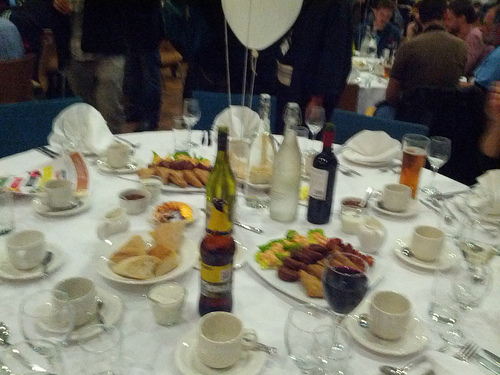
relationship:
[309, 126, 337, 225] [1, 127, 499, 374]
bottle on table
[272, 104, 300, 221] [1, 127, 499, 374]
clear bottle on table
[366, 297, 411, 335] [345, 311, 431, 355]
cup on small plate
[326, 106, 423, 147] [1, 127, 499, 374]
chair sitting at table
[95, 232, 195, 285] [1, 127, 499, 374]
plate on table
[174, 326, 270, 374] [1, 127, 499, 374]
plate on table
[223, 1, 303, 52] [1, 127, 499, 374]
white balloon at table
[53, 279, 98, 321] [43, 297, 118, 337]
cup on top of a plate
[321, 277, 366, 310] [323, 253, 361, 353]
red wine in glass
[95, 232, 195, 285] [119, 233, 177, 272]
plate with food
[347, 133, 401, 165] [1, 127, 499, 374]
napkin on table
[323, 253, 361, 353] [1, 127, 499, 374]
glass on table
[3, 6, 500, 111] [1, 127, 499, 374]
people around table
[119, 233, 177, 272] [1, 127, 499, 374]
food on table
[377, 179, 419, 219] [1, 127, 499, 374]
cup and saucer on table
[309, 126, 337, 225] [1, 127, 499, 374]
bottle of wine on table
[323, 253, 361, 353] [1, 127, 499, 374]
glass of wine on table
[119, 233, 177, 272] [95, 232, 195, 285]
bread on white plate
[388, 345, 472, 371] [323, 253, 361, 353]
silverware next to wine glass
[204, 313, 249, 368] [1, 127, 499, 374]
teacup on table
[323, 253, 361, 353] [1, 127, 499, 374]
glass of red wine on table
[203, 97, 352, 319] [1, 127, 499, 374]
wine bottles on table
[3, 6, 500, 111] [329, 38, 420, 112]
people sitting at a table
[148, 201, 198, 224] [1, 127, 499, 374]
bowl of chips on table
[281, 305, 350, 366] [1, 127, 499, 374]
drink on table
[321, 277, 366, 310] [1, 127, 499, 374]
red wine on table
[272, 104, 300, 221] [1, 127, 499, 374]
white wine on table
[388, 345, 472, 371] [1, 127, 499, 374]
silverware on table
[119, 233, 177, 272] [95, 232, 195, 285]
bread in dish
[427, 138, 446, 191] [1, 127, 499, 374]
wine glass on table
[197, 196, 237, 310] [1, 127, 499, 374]
beer bottle on table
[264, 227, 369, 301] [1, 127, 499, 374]
plate of food on table